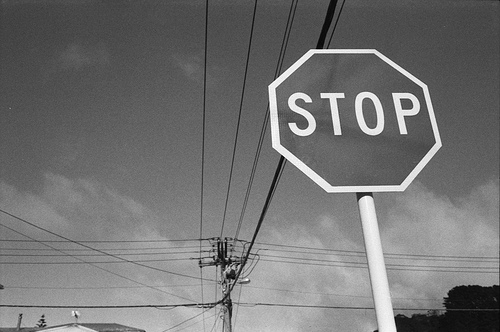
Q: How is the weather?
A: It is cloudy.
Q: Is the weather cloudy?
A: Yes, it is cloudy.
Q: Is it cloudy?
A: Yes, it is cloudy.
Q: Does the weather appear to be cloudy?
A: Yes, it is cloudy.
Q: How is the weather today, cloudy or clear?
A: It is cloudy.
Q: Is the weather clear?
A: No, it is cloudy.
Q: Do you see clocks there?
A: No, there are no clocks.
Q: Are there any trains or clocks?
A: No, there are no clocks or trains.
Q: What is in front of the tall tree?
A: The roof is in front of the tree.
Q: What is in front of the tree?
A: The roof is in front of the tree.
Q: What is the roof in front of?
A: The roof is in front of the tree.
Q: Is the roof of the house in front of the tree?
A: Yes, the roof is in front of the tree.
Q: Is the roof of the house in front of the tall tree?
A: Yes, the roof is in front of the tree.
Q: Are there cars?
A: No, there are no cars.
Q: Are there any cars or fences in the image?
A: No, there are no cars or fences.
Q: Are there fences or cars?
A: No, there are no cars or fences.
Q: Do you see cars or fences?
A: No, there are no cars or fences.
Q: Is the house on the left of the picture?
A: Yes, the house is on the left of the image.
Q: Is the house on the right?
A: No, the house is on the left of the image.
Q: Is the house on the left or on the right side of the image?
A: The house is on the left of the image.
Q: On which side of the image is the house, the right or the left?
A: The house is on the left of the image.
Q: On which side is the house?
A: The house is on the left of the image.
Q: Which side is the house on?
A: The house is on the left of the image.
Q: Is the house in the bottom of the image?
A: Yes, the house is in the bottom of the image.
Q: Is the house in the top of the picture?
A: No, the house is in the bottom of the image.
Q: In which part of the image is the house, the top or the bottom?
A: The house is in the bottom of the image.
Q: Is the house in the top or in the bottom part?
A: The house is in the bottom of the image.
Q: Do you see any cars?
A: No, there are no cars.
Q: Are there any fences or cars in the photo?
A: No, there are no cars or fences.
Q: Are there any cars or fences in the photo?
A: No, there are no cars or fences.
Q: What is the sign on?
A: The sign is on the pole.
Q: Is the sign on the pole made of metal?
A: Yes, the sign is on the pole.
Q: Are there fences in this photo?
A: No, there are no fences.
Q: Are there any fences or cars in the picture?
A: No, there are no fences or cars.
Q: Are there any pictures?
A: No, there are no pictures.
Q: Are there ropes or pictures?
A: No, there are no pictures or ropes.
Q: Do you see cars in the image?
A: No, there are no cars.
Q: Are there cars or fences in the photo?
A: No, there are no cars or fences.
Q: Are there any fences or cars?
A: No, there are no cars or fences.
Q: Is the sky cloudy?
A: Yes, the sky is cloudy.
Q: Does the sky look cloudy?
A: Yes, the sky is cloudy.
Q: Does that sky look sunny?
A: No, the sky is cloudy.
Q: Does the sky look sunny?
A: No, the sky is cloudy.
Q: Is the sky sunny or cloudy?
A: The sky is cloudy.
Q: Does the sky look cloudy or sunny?
A: The sky is cloudy.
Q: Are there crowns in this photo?
A: No, there are no crowns.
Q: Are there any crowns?
A: No, there are no crowns.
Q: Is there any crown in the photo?
A: No, there are no crowns.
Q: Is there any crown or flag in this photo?
A: No, there are no crowns or flags.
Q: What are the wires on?
A: The wires are on the pole.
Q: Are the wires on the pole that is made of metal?
A: Yes, the wires are on the pole.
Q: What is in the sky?
A: The wires are in the sky.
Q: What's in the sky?
A: The wires are in the sky.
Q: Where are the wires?
A: The wires are in the sky.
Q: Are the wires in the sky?
A: Yes, the wires are in the sky.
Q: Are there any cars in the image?
A: No, there are no cars.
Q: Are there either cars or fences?
A: No, there are no cars or fences.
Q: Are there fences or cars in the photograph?
A: No, there are no cars or fences.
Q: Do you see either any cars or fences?
A: No, there are no cars or fences.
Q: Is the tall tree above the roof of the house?
A: Yes, the tree is above the roof.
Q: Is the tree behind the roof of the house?
A: Yes, the tree is behind the roof.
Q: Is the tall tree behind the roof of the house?
A: Yes, the tree is behind the roof.